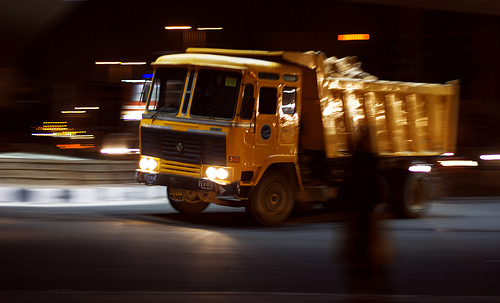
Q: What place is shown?
A: It is a street.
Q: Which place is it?
A: It is a street.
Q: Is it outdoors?
A: Yes, it is outdoors.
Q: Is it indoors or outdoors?
A: It is outdoors.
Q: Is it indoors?
A: No, it is outdoors.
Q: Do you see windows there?
A: Yes, there is a window.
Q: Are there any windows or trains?
A: Yes, there is a window.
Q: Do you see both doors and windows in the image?
A: Yes, there are both a window and a door.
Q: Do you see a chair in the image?
A: No, there are no chairs.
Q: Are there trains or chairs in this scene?
A: No, there are no chairs or trains.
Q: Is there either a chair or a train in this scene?
A: No, there are no chairs or trains.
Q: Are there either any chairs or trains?
A: No, there are no chairs or trains.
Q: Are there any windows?
A: Yes, there is a window.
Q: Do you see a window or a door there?
A: Yes, there is a window.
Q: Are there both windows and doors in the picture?
A: Yes, there are both a window and a door.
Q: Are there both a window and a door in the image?
A: Yes, there are both a window and a door.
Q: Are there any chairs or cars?
A: No, there are no cars or chairs.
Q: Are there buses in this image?
A: Yes, there is a bus.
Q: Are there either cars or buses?
A: Yes, there is a bus.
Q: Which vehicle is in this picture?
A: The vehicle is a bus.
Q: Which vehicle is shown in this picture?
A: The vehicle is a bus.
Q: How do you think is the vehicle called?
A: The vehicle is a bus.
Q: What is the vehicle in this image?
A: The vehicle is a bus.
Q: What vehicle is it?
A: The vehicle is a bus.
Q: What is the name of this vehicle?
A: This is a bus.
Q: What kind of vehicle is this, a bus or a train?
A: This is a bus.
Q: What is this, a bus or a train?
A: This is a bus.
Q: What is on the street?
A: The bus is on the street.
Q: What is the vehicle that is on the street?
A: The vehicle is a bus.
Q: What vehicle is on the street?
A: The vehicle is a bus.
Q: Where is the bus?
A: The bus is on the street.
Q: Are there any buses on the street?
A: Yes, there is a bus on the street.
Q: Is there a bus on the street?
A: Yes, there is a bus on the street.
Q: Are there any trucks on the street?
A: No, there is a bus on the street.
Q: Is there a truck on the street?
A: No, there is a bus on the street.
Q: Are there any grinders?
A: No, there are no grinders.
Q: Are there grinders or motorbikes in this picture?
A: No, there are no grinders or motorbikes.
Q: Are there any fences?
A: No, there are no fences.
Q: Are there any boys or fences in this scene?
A: No, there are no fences or boys.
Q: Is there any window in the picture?
A: Yes, there is a window.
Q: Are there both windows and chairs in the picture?
A: No, there is a window but no chairs.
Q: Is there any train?
A: No, there are no trains.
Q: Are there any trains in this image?
A: No, there are no trains.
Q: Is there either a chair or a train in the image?
A: No, there are no trains or chairs.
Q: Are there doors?
A: Yes, there is a door.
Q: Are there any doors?
A: Yes, there is a door.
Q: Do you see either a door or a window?
A: Yes, there is a door.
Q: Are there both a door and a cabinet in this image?
A: No, there is a door but no cabinets.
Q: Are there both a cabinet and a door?
A: No, there is a door but no cabinets.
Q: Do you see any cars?
A: No, there are no cars.